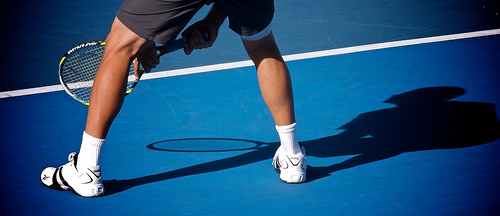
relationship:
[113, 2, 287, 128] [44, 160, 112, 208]
man has shoe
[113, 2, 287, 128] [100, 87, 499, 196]
man has shade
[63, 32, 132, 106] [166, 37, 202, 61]
racket has bottom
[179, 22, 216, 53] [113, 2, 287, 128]
hand of man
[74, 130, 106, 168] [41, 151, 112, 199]
sock and shoe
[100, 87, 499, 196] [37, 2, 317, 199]
shade of man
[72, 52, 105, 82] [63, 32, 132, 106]
strings on racket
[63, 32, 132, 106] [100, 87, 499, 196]
racket has shade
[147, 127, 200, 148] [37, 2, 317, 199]
shade of man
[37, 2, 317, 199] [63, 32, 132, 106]
man has racket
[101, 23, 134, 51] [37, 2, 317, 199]
knee of man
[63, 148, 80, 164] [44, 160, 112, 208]
lace of shoe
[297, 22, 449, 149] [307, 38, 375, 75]
court has ilnes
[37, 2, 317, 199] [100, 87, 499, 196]
man has shade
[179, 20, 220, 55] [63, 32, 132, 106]
hand on racket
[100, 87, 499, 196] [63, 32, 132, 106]
shade of racket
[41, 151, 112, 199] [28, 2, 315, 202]
shoe on tennis player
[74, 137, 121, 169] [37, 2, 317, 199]
sock on man